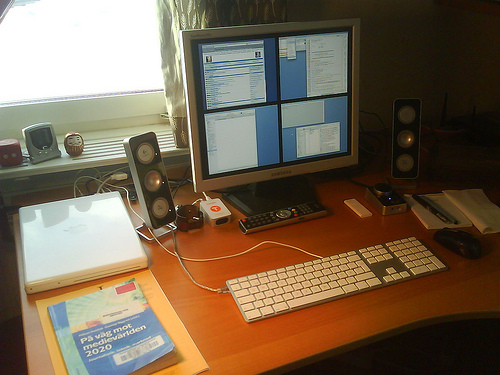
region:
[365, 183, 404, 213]
silver digital camera on the desk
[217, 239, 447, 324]
a computer keyboard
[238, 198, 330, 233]
remote control in front of the monitor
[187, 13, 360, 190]
a computer monitor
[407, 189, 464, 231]
note pad with a pen on top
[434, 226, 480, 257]
a black computer mouse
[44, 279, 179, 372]
a book in a foreign language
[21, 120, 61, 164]
silver digital clock on window sill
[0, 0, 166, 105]
a window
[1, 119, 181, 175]
a white windowsill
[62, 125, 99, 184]
a figuren on a window cile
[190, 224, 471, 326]
a white and silver keyboard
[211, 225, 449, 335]
a silver and white keyboard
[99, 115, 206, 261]
a silver speaker on a computer desk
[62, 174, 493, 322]
a brown computer desk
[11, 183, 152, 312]
a white apple laptop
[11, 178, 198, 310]
a white laptop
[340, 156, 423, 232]
a silver camera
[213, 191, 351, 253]
a silver tv remote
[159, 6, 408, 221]
a computer on a computer desk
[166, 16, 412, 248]
A SQUARE COMPUTER SCREEN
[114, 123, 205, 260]
SPEAKERS FOR COMPUTER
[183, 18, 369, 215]
COMPUTER SCREEN TURNED ON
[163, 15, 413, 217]
FOUR WINDOWS OPENED AT SAME TIME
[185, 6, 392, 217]
FOUR WINDOWS OPEN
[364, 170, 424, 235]
ON OFF SWITCH FOR SPEAKERS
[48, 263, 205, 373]
HOW TOO BOOK FOR COMPUTER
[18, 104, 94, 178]
CLOCK AND WEATHER RADIO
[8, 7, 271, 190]
OPEN WINDOW WITH SUN SHINING THROUGH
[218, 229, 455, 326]
ULTRA THIN KEYBOARD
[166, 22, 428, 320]
computer on a desk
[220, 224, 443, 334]
the keyboard is white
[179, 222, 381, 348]
the desk is made of wood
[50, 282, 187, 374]
book on a desk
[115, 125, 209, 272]
speakers on the desk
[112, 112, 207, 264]
the speakers are black and silver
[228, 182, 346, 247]
the remote is black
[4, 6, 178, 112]
the window is open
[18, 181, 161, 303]
the laptop is white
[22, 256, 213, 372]
yellow folder on top of the desk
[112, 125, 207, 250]
speakers are on the table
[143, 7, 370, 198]
the monitor is on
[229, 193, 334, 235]
the remote is on the desk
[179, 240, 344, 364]
the desk is tan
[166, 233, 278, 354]
the desk is made of wood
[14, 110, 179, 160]
the window sill is white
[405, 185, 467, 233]
a pen on the paper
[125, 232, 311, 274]
wires from the keyboard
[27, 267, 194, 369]
a book on the desk